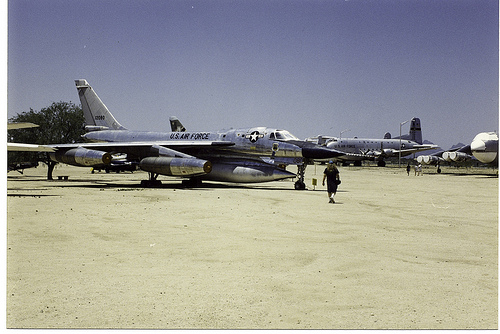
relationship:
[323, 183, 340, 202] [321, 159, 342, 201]
legs of person